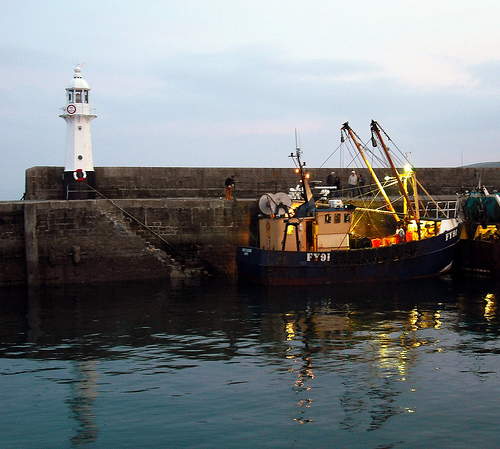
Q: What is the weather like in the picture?
A: It is cloudy.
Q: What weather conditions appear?
A: It is cloudy.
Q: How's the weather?
A: It is cloudy.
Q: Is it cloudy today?
A: Yes, it is cloudy.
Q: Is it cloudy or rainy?
A: It is cloudy.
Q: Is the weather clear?
A: No, it is cloudy.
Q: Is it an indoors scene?
A: Yes, it is indoors.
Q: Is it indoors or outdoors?
A: It is indoors.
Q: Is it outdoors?
A: No, it is indoors.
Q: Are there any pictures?
A: No, there are no pictures.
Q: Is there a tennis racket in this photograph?
A: No, there are no rackets.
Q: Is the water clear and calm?
A: Yes, the water is clear and calm.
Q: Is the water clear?
A: Yes, the water is clear.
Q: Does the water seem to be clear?
A: Yes, the water is clear.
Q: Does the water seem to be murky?
A: No, the water is clear.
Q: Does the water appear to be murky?
A: No, the water is clear.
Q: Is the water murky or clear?
A: The water is clear.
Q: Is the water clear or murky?
A: The water is clear.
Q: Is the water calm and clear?
A: Yes, the water is calm and clear.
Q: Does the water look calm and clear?
A: Yes, the water is calm and clear.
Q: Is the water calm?
A: Yes, the water is calm.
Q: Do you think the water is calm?
A: Yes, the water is calm.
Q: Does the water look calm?
A: Yes, the water is calm.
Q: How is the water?
A: The water is calm.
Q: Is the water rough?
A: No, the water is calm.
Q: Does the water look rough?
A: No, the water is calm.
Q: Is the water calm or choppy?
A: The water is calm.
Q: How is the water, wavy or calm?
A: The water is calm.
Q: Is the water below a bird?
A: No, the water is below the boat.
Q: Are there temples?
A: No, there are no temples.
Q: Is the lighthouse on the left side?
A: Yes, the lighthouse is on the left of the image.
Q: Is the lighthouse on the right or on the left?
A: The lighthouse is on the left of the image.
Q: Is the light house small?
A: Yes, the light house is small.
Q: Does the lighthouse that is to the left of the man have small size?
A: Yes, the lighthouse is small.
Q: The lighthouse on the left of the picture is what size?
A: The lighthouse is small.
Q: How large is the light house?
A: The light house is small.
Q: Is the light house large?
A: No, the light house is small.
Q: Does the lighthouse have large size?
A: No, the lighthouse is small.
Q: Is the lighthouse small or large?
A: The lighthouse is small.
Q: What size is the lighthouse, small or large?
A: The lighthouse is small.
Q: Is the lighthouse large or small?
A: The lighthouse is small.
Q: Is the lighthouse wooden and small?
A: Yes, the lighthouse is wooden and small.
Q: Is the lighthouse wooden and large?
A: No, the lighthouse is wooden but small.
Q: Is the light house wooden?
A: Yes, the light house is wooden.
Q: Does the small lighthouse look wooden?
A: Yes, the light house is wooden.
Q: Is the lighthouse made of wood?
A: Yes, the lighthouse is made of wood.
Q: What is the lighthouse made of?
A: The lighthouse is made of wood.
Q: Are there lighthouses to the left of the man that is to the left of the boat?
A: Yes, there is a lighthouse to the left of the man.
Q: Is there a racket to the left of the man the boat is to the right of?
A: No, there is a lighthouse to the left of the man.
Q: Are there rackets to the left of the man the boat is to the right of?
A: No, there is a lighthouse to the left of the man.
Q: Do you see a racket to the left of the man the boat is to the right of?
A: No, there is a lighthouse to the left of the man.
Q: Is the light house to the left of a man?
A: Yes, the light house is to the left of a man.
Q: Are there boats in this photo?
A: Yes, there is a boat.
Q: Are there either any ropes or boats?
A: Yes, there is a boat.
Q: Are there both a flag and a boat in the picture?
A: No, there is a boat but no flags.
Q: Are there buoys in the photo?
A: No, there are no buoys.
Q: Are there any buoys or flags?
A: No, there are no buoys or flags.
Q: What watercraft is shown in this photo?
A: The watercraft is a boat.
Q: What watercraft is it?
A: The watercraft is a boat.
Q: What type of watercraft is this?
A: This is a boat.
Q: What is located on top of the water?
A: The boat is on top of the water.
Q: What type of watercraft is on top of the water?
A: The watercraft is a boat.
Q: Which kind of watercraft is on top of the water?
A: The watercraft is a boat.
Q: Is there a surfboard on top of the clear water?
A: No, there is a boat on top of the water.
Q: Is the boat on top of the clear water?
A: Yes, the boat is on top of the water.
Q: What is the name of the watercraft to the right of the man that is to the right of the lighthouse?
A: The watercraft is a boat.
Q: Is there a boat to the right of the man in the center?
A: Yes, there is a boat to the right of the man.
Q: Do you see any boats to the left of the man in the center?
A: No, the boat is to the right of the man.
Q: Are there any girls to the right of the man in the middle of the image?
A: No, there is a boat to the right of the man.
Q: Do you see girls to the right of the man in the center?
A: No, there is a boat to the right of the man.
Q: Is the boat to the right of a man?
A: Yes, the boat is to the right of a man.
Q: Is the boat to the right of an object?
A: No, the boat is to the right of a man.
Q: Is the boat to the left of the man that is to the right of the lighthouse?
A: No, the boat is to the right of the man.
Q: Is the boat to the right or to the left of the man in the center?
A: The boat is to the right of the man.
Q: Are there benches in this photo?
A: No, there are no benches.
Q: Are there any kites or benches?
A: No, there are no benches or kites.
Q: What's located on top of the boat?
A: The crane is on top of the boat.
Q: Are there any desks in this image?
A: No, there are no desks.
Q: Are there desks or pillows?
A: No, there are no desks or pillows.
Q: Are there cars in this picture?
A: No, there are no cars.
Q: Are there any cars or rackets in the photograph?
A: No, there are no cars or rackets.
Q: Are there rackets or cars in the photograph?
A: No, there are no cars or rackets.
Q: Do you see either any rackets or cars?
A: No, there are no cars or rackets.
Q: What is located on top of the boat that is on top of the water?
A: The crane is on top of the boat.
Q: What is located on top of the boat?
A: The crane is on top of the boat.